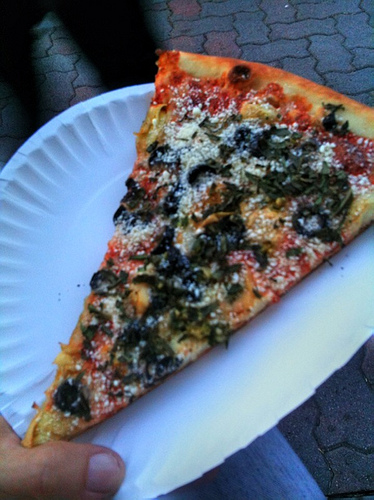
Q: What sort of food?
A: Pizza.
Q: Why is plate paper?
A: Disposable.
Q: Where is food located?
A: On plate.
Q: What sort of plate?
A: Paper.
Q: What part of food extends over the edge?
A: Crust.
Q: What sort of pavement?
A: Shaped pink and grey bricks.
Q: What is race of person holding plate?
A: Caucasian.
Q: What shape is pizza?
A: Triangle.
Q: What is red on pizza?
A: Tomato sauce.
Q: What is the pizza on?
A: Paper plate.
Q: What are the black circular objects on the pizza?
A: Black olives.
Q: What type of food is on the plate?
A: Pizza.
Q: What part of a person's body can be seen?
A: Thumb.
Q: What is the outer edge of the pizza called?
A: Crust.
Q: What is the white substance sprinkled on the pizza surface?
A: Parmesan cheese.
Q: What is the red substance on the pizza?
A: Sauce.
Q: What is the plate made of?
A: Paper.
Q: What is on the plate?
A: Pizza.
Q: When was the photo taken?
A: Night.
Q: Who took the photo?
A: Person.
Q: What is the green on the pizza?
A: Spinach.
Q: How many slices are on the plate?
A: One.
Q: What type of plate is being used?
A: Paper.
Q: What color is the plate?
A: White.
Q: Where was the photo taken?
A: On a sidewalk.